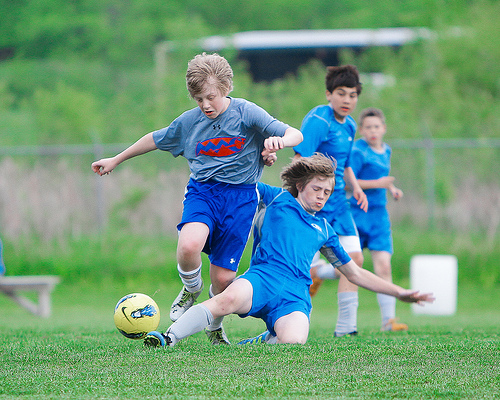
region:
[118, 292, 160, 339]
a yellow and blue soccer ball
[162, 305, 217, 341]
a gray shin guard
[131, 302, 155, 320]
a blue design on a soccer ball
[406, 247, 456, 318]
a white cooler in the grass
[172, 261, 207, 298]
a white knee high sock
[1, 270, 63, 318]
the right end of a wooden bench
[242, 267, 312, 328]
a blue pair of soccer shorts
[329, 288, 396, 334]
gray tall socks on a player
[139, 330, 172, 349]
a blue soccer cleat shoe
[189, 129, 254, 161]
a blue and red design on the front of a shirt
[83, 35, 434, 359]
boys playing soccer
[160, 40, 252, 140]
this boy looks really intent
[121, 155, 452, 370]
this boy is falling down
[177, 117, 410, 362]
the boys are all wearing blue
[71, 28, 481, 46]
the background is all out of focus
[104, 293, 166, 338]
the ball is yellow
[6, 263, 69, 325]
a bench in the background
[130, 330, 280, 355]
this boy is wearing blue spikes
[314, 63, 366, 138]
this boy has very dark hair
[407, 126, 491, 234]
a fence in the background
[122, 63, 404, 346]
These kids are playing soccer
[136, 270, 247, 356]
This kid is kicking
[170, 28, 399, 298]
They are young kids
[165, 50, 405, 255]
Young boys playing soccer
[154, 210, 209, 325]
This kid is about to kick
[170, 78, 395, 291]
Their uniforms are blue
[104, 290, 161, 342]
This is a soccer ball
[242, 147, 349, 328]
This kid is falling to kick ball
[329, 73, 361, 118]
This kid is making a face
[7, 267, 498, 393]
This is a soccer field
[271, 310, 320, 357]
he fell on his knee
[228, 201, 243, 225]
the shorts are bright blue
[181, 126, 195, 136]
the shirt is gray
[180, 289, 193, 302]
the laces are green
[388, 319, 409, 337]
the shoes are orange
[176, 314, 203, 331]
the socks are white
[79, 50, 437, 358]
a group of boys playing soccer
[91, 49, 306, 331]
a boy playing soccer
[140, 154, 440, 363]
a boy sliding to kick a soccer ball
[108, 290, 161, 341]
a yellow soccer ball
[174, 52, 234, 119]
the head of a boy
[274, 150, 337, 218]
the head of a boy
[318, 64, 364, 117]
the head of a boy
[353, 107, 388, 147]
the head of a boy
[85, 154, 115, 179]
the hand of a boy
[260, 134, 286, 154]
the hand of a boy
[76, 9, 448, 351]
a group of kids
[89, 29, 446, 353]
the kids are playing soccer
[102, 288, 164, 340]
a yellow soccer ball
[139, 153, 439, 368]
boy on the ground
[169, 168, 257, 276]
blue pair of shorts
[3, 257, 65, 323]
bench on the side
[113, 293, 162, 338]
a yellow, black and blue soccer ball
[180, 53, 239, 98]
a boy's short cut hair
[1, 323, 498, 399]
a section of green grass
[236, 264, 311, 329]
a boy's blue shorts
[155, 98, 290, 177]
a boy's short sleeve shirt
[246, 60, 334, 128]
green tree leaves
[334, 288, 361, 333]
a boy's long gray sock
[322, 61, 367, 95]
short cut dark hair